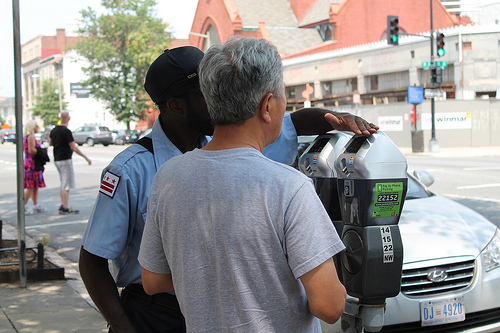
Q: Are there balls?
A: No, there are no balls.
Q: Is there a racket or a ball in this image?
A: No, there are no balls or rackets.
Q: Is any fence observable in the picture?
A: No, there are no fences.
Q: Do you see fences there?
A: No, there are no fences.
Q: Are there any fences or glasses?
A: No, there are no fences or glasses.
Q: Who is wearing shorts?
A: The man is wearing shorts.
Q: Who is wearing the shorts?
A: The man is wearing shorts.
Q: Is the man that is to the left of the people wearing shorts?
A: Yes, the man is wearing shorts.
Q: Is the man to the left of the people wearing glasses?
A: No, the man is wearing shorts.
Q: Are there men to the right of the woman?
A: Yes, there is a man to the right of the woman.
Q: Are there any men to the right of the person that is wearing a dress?
A: Yes, there is a man to the right of the woman.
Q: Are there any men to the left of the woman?
A: No, the man is to the right of the woman.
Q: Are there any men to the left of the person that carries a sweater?
A: No, the man is to the right of the woman.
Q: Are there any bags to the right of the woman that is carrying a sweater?
A: No, there is a man to the right of the woman.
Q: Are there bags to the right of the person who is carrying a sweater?
A: No, there is a man to the right of the woman.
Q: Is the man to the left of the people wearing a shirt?
A: Yes, the man is wearing a shirt.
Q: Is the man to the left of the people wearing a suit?
A: No, the man is wearing a shirt.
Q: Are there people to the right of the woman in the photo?
A: Yes, there are people to the right of the woman.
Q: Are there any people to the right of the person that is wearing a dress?
A: Yes, there are people to the right of the woman.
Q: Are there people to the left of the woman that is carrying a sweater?
A: No, the people are to the right of the woman.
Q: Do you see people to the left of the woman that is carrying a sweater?
A: No, the people are to the right of the woman.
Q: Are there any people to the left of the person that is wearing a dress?
A: No, the people are to the right of the woman.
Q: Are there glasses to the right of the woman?
A: No, there are people to the right of the woman.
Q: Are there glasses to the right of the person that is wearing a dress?
A: No, there are people to the right of the woman.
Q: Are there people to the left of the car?
A: Yes, there are people to the left of the car.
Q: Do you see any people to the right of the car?
A: No, the people are to the left of the car.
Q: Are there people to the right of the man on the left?
A: Yes, there are people to the right of the man.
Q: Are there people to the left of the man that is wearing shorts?
A: No, the people are to the right of the man.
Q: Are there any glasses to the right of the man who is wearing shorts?
A: No, there are people to the right of the man.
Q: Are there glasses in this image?
A: No, there are no glasses.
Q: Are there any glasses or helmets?
A: No, there are no glasses or helmets.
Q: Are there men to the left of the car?
A: Yes, there is a man to the left of the car.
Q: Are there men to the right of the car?
A: No, the man is to the left of the car.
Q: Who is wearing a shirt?
A: The man is wearing a shirt.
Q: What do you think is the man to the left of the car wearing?
A: The man is wearing a shirt.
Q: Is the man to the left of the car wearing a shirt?
A: Yes, the man is wearing a shirt.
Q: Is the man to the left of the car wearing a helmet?
A: No, the man is wearing a shirt.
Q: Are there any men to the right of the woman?
A: Yes, there is a man to the right of the woman.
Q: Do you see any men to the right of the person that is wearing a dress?
A: Yes, there is a man to the right of the woman.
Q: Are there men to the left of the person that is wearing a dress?
A: No, the man is to the right of the woman.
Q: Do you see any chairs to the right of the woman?
A: No, there is a man to the right of the woman.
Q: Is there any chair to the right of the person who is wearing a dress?
A: No, there is a man to the right of the woman.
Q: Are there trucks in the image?
A: No, there are no trucks.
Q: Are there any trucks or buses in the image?
A: No, there are no trucks or buses.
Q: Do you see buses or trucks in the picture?
A: No, there are no trucks or buses.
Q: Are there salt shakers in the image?
A: No, there are no salt shakers.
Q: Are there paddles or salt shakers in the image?
A: No, there are no salt shakers or paddles.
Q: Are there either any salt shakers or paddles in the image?
A: No, there are no salt shakers or paddles.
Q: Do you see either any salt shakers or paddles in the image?
A: No, there are no salt shakers or paddles.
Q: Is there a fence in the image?
A: No, there are no fences.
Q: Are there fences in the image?
A: No, there are no fences.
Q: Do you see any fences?
A: No, there are no fences.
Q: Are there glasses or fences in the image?
A: No, there are no fences or glasses.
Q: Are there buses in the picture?
A: No, there are no buses.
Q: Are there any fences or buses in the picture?
A: No, there are no buses or fences.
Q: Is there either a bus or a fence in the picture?
A: No, there are no buses or fences.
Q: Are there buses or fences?
A: No, there are no buses or fences.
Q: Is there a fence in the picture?
A: No, there are no fences.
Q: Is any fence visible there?
A: No, there are no fences.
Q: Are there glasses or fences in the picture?
A: No, there are no fences or glasses.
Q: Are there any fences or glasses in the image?
A: No, there are no fences or glasses.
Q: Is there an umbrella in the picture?
A: No, there are no umbrellas.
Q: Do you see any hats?
A: Yes, there is a hat.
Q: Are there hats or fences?
A: Yes, there is a hat.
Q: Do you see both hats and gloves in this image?
A: No, there is a hat but no gloves.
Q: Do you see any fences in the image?
A: No, there are no fences.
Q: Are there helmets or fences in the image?
A: No, there are no fences or helmets.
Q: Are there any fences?
A: No, there are no fences.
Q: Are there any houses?
A: No, there are no houses.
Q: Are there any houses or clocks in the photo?
A: No, there are no houses or clocks.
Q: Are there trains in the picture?
A: No, there are no trains.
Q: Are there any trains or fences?
A: No, there are no trains or fences.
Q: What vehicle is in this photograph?
A: The vehicle is a car.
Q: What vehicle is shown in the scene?
A: The vehicle is a car.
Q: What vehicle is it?
A: The vehicle is a car.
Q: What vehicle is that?
A: That is a car.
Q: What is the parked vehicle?
A: The vehicle is a car.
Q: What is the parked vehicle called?
A: The vehicle is a car.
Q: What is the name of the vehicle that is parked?
A: The vehicle is a car.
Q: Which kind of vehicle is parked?
A: The vehicle is a car.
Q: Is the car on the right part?
A: Yes, the car is on the right of the image.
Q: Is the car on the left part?
A: No, the car is on the right of the image.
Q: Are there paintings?
A: No, there are no paintings.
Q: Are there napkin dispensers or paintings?
A: No, there are no paintings or napkin dispensers.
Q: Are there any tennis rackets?
A: No, there are no tennis rackets.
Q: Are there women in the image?
A: Yes, there is a woman.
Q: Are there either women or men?
A: Yes, there is a woman.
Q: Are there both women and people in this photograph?
A: Yes, there are both a woman and a person.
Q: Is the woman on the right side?
A: No, the woman is on the left of the image.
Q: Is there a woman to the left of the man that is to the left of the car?
A: Yes, there is a woman to the left of the man.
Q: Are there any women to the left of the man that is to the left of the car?
A: Yes, there is a woman to the left of the man.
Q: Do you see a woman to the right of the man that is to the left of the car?
A: No, the woman is to the left of the man.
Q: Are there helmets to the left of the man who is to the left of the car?
A: No, there is a woman to the left of the man.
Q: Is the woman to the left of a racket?
A: No, the woman is to the left of a man.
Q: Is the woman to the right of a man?
A: No, the woman is to the left of a man.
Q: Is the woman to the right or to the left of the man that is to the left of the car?
A: The woman is to the left of the man.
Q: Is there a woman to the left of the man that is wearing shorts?
A: Yes, there is a woman to the left of the man.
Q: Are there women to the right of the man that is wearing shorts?
A: No, the woman is to the left of the man.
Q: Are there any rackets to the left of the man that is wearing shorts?
A: No, there is a woman to the left of the man.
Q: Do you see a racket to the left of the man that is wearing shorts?
A: No, there is a woman to the left of the man.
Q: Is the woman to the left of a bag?
A: No, the woman is to the left of the man.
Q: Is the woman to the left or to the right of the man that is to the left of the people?
A: The woman is to the left of the man.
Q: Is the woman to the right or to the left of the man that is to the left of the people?
A: The woman is to the left of the man.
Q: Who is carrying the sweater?
A: The woman is carrying the sweater.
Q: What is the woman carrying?
A: The woman is carrying a sweater.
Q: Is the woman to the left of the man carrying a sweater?
A: Yes, the woman is carrying a sweater.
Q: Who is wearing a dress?
A: The woman is wearing a dress.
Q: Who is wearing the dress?
A: The woman is wearing a dress.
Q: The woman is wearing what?
A: The woman is wearing a dress.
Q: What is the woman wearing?
A: The woman is wearing a dress.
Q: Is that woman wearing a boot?
A: No, the woman is wearing a dress.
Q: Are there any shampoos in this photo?
A: No, there are no shampoos.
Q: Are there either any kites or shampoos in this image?
A: No, there are no shampoos or kites.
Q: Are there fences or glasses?
A: No, there are no fences or glasses.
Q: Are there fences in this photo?
A: No, there are no fences.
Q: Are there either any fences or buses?
A: No, there are no fences or buses.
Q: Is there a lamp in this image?
A: No, there are no lamps.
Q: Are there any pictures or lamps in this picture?
A: No, there are no lamps or pictures.